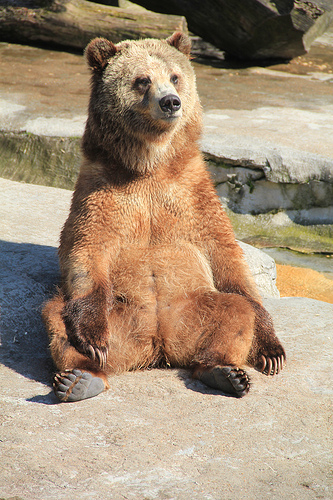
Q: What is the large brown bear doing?
A: Sitting down.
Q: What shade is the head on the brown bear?
A: Brown.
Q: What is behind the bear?
A: Piece of brown log.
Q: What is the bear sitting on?
A: A rock.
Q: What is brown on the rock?
A: A bear.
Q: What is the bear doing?
A: Sitting down.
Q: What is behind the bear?
A: Its shadow.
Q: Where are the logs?
A: Behind the bear.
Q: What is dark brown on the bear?
A: Its snout.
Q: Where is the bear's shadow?
A: Behind the bear.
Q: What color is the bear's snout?
A: White.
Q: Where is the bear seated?
A: On a rock.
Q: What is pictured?
A: A bear.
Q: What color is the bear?
A: Brown.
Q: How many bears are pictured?
A: One.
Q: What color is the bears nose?
A: Black.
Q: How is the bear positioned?
A: Seated.